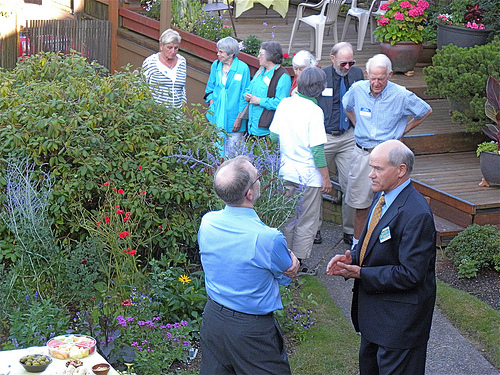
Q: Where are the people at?
A: Garden.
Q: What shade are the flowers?
A: Red.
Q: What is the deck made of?
A: Wood.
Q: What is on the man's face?
A: Glasses.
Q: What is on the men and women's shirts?
A: Name tags.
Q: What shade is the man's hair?
A: White.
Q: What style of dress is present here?
A: Formal.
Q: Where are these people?
A: Garden.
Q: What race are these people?
A: White.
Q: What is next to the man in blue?
A: Bush.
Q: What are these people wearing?
A: Name Tags.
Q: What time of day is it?
A: Evening.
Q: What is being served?
A: Food.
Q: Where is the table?
A: Behind the men.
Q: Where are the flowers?
A: The garden.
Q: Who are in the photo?
A: Elderly people.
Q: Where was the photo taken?
A: Garden.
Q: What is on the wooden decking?
A: Potted plants.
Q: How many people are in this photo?
A: Nine.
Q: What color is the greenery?
A: Green.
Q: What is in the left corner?
A: Table.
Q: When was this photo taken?
A: Daytime.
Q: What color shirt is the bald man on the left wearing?
A: Blue.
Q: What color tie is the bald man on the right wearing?
A: Orange.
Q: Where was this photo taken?
A: Party.